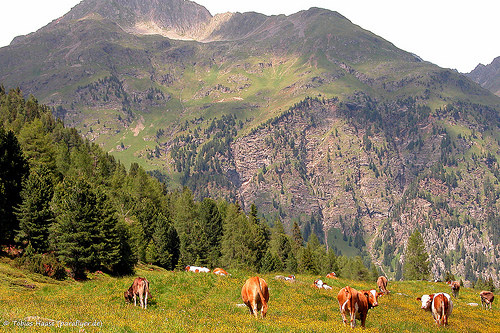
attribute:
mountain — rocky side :
[0, 0, 498, 287]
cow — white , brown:
[416, 292, 453, 326]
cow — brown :
[336, 285, 381, 329]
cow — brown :
[233, 271, 268, 322]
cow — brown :
[414, 290, 455, 330]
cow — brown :
[121, 272, 155, 308]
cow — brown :
[472, 287, 494, 314]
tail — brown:
[251, 272, 268, 317]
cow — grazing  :
[120, 273, 152, 310]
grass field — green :
[1, 250, 498, 331]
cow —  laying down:
[185, 265, 209, 273]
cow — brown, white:
[310, 275, 382, 331]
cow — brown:
[124, 275, 159, 310]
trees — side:
[46, 109, 249, 286]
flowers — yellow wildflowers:
[371, 289, 429, 323]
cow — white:
[179, 263, 211, 273]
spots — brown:
[192, 268, 200, 273]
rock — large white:
[464, 297, 481, 312]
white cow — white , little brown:
[331, 284, 383, 322]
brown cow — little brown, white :
[420, 285, 452, 317]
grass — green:
[250, 74, 281, 99]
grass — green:
[144, 114, 172, 128]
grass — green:
[270, 294, 335, 331]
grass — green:
[152, 278, 236, 330]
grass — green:
[2, 286, 121, 317]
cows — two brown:
[308, 232, 470, 307]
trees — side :
[49, 140, 325, 252]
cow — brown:
[333, 282, 380, 327]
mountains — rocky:
[0, 1, 498, 158]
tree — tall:
[50, 175, 127, 281]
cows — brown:
[239, 272, 394, 329]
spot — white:
[369, 285, 377, 296]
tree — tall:
[393, 223, 440, 284]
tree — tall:
[260, 250, 282, 279]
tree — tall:
[169, 190, 209, 270]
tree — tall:
[217, 191, 264, 278]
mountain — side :
[201, 35, 445, 202]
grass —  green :
[139, 262, 356, 330]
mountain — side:
[165, 15, 403, 205]